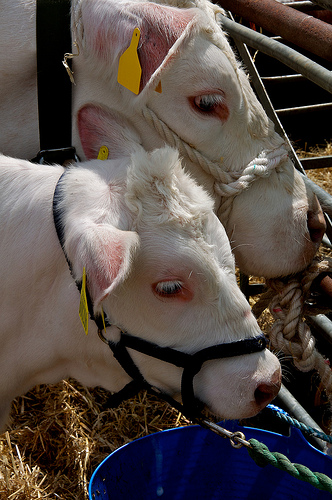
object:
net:
[237, 2, 332, 180]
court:
[204, 124, 324, 371]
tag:
[78, 264, 89, 337]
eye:
[185, 89, 232, 125]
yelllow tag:
[117, 21, 143, 96]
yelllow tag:
[77, 268, 90, 336]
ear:
[119, 2, 199, 114]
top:
[66, 415, 95, 471]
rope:
[245, 436, 332, 497]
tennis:
[52, 5, 292, 418]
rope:
[139, 103, 292, 241]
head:
[72, 2, 328, 281]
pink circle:
[148, 273, 194, 304]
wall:
[177, 66, 207, 91]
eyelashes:
[156, 279, 184, 292]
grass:
[16, 427, 77, 490]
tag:
[117, 28, 143, 96]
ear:
[78, 221, 144, 315]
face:
[157, 0, 326, 279]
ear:
[73, 100, 142, 168]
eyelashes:
[194, 93, 226, 106]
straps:
[54, 161, 272, 420]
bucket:
[87, 421, 330, 499]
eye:
[152, 276, 195, 308]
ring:
[151, 275, 189, 302]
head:
[74, 147, 284, 432]